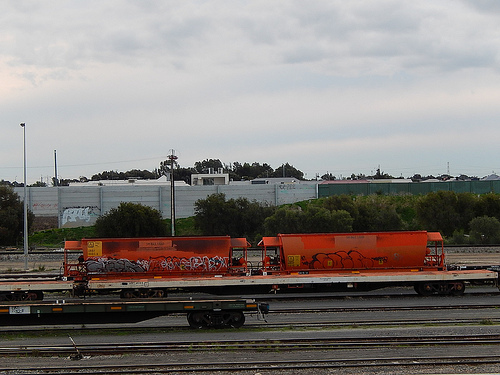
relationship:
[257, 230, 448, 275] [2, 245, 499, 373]
train car on platform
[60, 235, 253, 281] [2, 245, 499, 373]
train car on platform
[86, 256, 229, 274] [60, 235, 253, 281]
graffiti on train car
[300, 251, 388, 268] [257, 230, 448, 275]
graffiti on train car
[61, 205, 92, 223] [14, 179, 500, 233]
graffiti on a wall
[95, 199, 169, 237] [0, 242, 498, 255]
bush next to tracks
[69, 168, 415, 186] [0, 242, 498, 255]
building by tracks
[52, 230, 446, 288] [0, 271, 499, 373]
train on tracks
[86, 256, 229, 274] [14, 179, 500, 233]
graffiti on wall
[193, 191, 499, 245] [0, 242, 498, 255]
trees next to tracks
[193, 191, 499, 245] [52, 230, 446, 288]
trees behind train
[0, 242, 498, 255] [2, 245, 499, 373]
tracks on platform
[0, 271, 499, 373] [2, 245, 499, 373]
tracks on platform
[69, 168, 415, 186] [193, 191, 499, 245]
building behind trees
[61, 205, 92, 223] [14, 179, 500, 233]
graffiti on wall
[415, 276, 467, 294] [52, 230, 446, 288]
wheels on train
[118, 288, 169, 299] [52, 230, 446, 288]
wheels on train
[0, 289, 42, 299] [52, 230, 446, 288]
wheels on train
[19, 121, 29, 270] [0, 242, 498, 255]
light post next to tracks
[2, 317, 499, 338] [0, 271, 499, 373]
grass on tracks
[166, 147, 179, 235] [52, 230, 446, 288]
power line behind train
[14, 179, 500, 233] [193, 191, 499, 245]
wall behind trees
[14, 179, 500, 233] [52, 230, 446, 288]
wall behind train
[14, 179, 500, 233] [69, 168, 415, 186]
wall in front of building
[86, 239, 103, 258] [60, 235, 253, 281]
sticker on train car